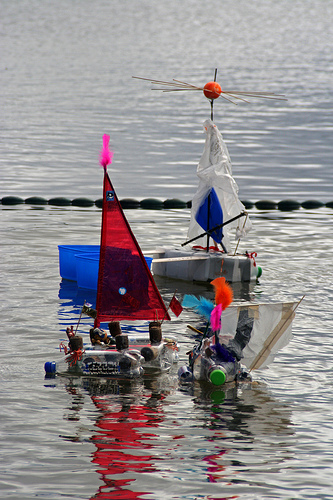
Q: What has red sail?
A: Boat.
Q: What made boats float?
A: Bottles.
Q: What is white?
A: Sail.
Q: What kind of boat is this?
A: Toy.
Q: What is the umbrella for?
A: Toy boat.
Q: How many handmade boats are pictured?
A: Three.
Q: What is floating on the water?
A: Handmade boats.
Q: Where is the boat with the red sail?
A: In front on the left.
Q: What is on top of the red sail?
A: A pink feather.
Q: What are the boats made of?
A: Empty plastic bottles.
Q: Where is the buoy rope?
A: Behind the boats.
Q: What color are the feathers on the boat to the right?
A: Blue, orange, and pink.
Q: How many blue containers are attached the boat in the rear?
A: Two.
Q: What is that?
A: A sailboat.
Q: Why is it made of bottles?
A: To float easy.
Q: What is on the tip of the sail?
A: A pink feather.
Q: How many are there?
A: 3.